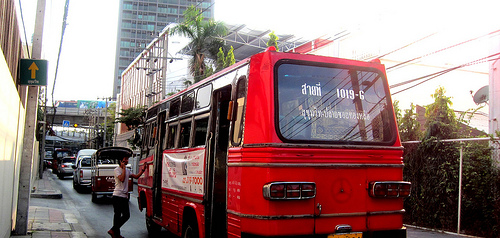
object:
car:
[88, 146, 132, 203]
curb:
[45, 180, 68, 202]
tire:
[181, 209, 196, 236]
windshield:
[273, 57, 402, 147]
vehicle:
[85, 143, 134, 205]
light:
[264, 178, 321, 200]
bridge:
[44, 103, 112, 134]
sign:
[157, 150, 220, 202]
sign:
[15, 57, 49, 87]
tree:
[166, 2, 230, 74]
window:
[165, 94, 182, 120]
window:
[192, 80, 216, 110]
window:
[163, 117, 178, 151]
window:
[174, 115, 192, 149]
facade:
[108, 23, 173, 132]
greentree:
[401, 129, 499, 237]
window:
[132, 51, 424, 236]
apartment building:
[90, 5, 222, 80]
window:
[147, 127, 162, 147]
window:
[179, 89, 196, 114]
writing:
[293, 75, 374, 122]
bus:
[123, 44, 412, 232]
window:
[272, 56, 397, 143]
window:
[179, 122, 191, 146]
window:
[149, 122, 157, 143]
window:
[141, 122, 147, 144]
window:
[226, 71, 250, 151]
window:
[192, 115, 208, 145]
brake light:
[267, 169, 360, 225]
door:
[202, 90, 237, 234]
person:
[98, 156, 144, 232]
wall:
[13, 30, 81, 228]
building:
[0, 6, 90, 235]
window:
[140, 107, 162, 117]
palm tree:
[172, 2, 232, 85]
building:
[106, 22, 240, 102]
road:
[50, 138, 430, 235]